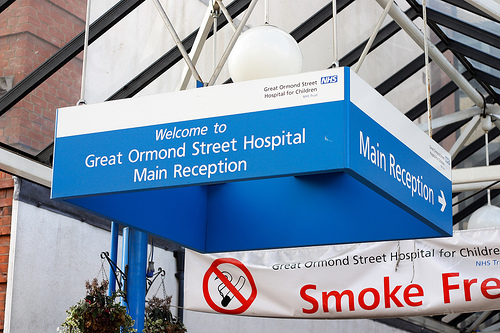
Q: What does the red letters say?
A: Smoke free.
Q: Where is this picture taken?
A: Great Ormond Street Hospital.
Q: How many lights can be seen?
A: 2.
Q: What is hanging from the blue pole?
A: Flowers.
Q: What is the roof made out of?
A: Windows.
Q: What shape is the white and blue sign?
A: Square.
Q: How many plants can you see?
A: 2.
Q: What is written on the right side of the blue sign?
A: Main Reception.